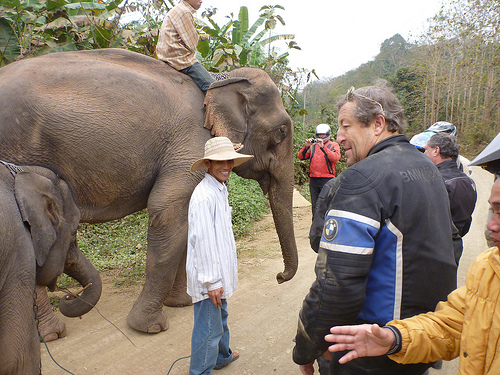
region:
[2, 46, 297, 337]
an elephant on a dirt road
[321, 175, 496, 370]
a man holding his right arm out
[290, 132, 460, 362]
man wearing a jacket with a car brand logo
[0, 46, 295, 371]
man standing in front of an elephant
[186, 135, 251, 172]
man wearing a tan hat with a wide brim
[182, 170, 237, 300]
man wearing a loose-fitting shirt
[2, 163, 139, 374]
elephant holding twigs with its trunk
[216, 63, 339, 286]
man photographing elephant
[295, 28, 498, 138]
tree covered hill in the distance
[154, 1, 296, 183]
person riding behind elephant's head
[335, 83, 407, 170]
Man wearing glasses on head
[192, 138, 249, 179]
Man wearing sun hat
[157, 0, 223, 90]
Man riding an elephant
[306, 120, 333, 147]
Man taking a picture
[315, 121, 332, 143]
Man wearing a helmet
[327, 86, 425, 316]
Man wearing black coat with blue and white design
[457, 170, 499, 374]
Man wearing yellow coat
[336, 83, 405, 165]
Man with gray hair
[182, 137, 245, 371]
Man wearing baggy clothes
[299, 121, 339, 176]
Man wearing red coat with black stripes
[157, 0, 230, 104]
person sitting on top of the elephant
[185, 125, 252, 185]
man wearing a floppy hat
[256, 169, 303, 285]
long elephant trunk hanging down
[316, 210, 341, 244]
bmw symbol on the man's jacket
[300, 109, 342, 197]
person taking a picture in a red jacket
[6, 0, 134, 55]
big green leaves behind the elephants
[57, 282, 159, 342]
sticks in the elephants mouth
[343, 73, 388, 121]
glasses on top of the man's head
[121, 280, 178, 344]
large foot of elephant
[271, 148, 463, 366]
black and blue jacket on the man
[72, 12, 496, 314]
people in the photo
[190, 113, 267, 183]
man with a hat on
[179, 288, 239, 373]
blue pants on man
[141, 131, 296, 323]
man in a shirt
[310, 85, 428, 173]
head of the man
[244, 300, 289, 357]
ground under the man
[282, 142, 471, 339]
jacket on the man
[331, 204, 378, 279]
blue and white part of jacket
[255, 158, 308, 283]
trunk of the elephant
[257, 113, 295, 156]
eye of the elephant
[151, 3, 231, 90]
man riding on elephant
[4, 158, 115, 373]
smaller elephant walking down the street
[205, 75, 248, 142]
floppy ear of elephant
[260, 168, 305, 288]
Long trunk of elephant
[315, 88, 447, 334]
Man in a blue and black coat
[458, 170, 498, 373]
man in yellow coat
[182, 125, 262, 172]
Straw hat on man' head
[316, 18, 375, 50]
cloudy sky off in the distance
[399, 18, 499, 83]
clump of skinny trees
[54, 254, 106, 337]
elephant with twig in his trunk